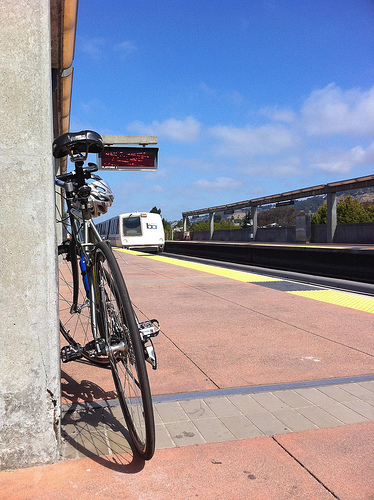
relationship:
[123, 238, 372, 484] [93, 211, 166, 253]
platform for stain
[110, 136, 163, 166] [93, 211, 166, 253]
sign over stain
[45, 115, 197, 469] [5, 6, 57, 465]
bike against wall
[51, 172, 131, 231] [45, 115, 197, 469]
helmet on bike